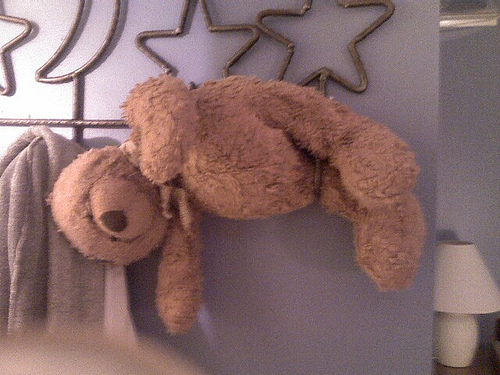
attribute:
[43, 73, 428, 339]
teddy bear — brown, in bad shape, giant, stuffed, fluffy, hanging, adorable, stitched up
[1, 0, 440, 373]
wall — lit, pale lavender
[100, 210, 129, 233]
nose — dark brown, artificial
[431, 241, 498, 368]
lamp — white, small, to right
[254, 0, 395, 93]
star — iron, decoration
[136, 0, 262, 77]
star — iron, decoration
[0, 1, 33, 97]
star — iron, decoration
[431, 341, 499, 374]
table — wooden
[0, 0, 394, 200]
rod — metal, coat rack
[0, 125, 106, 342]
cloth — woolen, jacket, robe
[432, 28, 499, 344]
wall — plain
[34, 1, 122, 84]
moon — iron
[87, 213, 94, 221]
eye — dark brown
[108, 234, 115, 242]
eye — dark brown